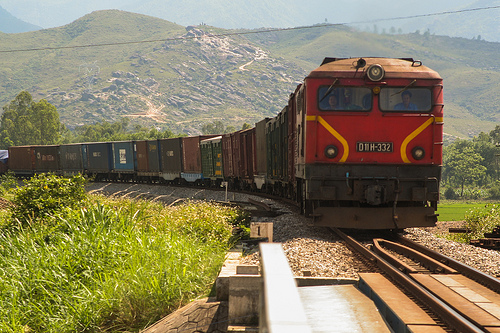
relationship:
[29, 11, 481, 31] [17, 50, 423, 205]
mountains behind train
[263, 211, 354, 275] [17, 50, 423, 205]
gravel under train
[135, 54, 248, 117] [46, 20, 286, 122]
rocks on hill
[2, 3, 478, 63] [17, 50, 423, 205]
wire above train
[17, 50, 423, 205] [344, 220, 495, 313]
train moves on tracks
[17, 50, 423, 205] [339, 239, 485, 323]
train approaches trestle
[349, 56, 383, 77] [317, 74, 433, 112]
horn above windows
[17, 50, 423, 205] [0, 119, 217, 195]
train pulls freight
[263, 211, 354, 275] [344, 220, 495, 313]
gravel under tracks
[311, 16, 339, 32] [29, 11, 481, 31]
tower atop mountains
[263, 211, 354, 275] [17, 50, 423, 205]
gravel near train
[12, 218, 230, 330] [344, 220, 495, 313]
grass grows along tracks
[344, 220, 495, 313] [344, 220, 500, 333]
tracks have tracks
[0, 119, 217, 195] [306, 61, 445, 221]
freight behind engine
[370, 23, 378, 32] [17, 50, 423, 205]
tree behind train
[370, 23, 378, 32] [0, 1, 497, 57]
tree in distance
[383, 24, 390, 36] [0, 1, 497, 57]
tree in distance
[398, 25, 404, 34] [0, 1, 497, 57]
tree in distance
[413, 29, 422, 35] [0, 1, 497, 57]
tree in distance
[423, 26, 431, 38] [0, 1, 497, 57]
tree in distance